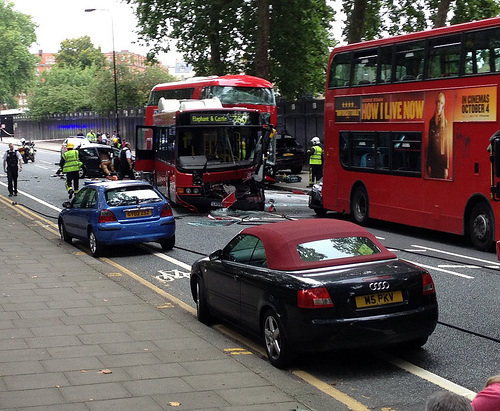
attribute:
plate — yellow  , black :
[354, 288, 406, 308]